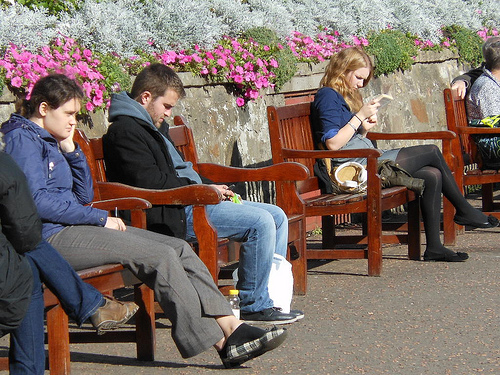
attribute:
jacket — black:
[98, 102, 199, 226]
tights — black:
[396, 144, 489, 259]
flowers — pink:
[1, 19, 498, 109]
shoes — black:
[219, 318, 286, 366]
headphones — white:
[332, 156, 369, 196]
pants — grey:
[38, 217, 242, 364]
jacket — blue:
[312, 86, 362, 154]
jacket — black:
[0, 149, 41, 337]